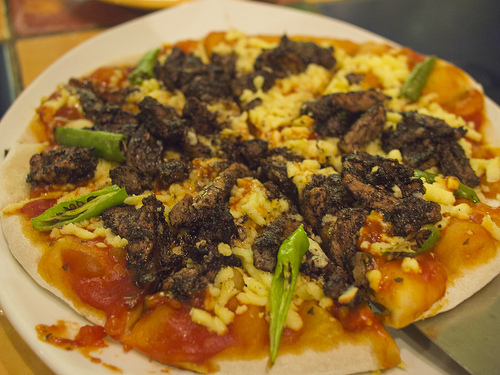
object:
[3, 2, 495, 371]
dish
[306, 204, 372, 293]
meat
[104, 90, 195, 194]
chicken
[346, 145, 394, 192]
meat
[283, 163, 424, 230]
slice pizza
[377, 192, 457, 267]
spice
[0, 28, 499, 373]
pizza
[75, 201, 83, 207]
seeds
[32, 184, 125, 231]
pepper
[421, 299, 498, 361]
surface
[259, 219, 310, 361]
green pepper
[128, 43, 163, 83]
green pepper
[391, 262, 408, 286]
herb piece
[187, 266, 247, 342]
yellow rice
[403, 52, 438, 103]
pepper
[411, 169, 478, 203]
pepper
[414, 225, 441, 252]
pepper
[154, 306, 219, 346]
salsa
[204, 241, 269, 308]
cheese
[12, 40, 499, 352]
burrito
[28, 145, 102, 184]
beef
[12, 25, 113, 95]
tile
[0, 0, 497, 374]
white plate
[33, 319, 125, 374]
sauce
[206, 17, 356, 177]
slice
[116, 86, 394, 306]
topping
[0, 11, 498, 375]
table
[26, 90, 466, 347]
taco